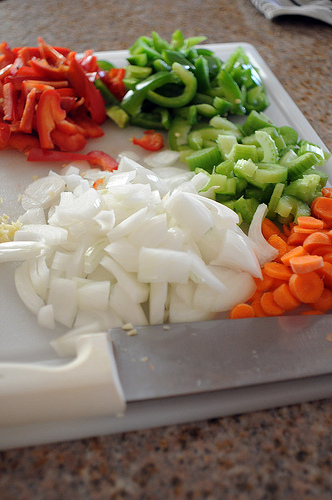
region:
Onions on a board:
[1, 157, 277, 350]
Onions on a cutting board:
[0, 150, 277, 356]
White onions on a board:
[0, 147, 276, 359]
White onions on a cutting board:
[1, 148, 277, 358]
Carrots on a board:
[221, 184, 330, 322]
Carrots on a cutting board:
[226, 181, 328, 320]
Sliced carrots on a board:
[229, 181, 323, 321]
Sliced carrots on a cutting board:
[228, 179, 331, 319]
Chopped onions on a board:
[6, 150, 278, 359]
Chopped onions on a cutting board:
[0, 148, 281, 357]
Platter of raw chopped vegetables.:
[4, 22, 318, 322]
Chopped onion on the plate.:
[20, 151, 256, 333]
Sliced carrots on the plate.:
[255, 187, 328, 312]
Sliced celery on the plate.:
[206, 104, 320, 205]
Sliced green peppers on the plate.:
[118, 11, 270, 125]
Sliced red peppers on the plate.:
[4, 27, 113, 161]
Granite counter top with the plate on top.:
[170, 418, 308, 488]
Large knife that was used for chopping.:
[10, 303, 326, 424]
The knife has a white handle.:
[6, 302, 328, 410]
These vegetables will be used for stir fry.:
[11, 37, 324, 317]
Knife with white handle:
[0, 320, 329, 422]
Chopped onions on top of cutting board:
[0, 162, 260, 325]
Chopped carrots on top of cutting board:
[231, 186, 329, 317]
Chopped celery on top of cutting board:
[171, 109, 328, 217]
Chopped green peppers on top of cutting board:
[102, 30, 269, 127]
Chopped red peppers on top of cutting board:
[1, 37, 163, 165]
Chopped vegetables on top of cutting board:
[2, 31, 331, 325]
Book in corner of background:
[251, 1, 330, 30]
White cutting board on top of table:
[1, 40, 330, 447]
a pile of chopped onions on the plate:
[27, 168, 177, 322]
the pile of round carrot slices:
[256, 215, 326, 316]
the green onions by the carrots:
[200, 116, 320, 189]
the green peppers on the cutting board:
[121, 25, 265, 119]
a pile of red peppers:
[0, 22, 114, 157]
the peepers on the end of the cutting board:
[0, 21, 259, 119]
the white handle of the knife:
[0, 332, 119, 410]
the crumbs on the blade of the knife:
[122, 316, 178, 336]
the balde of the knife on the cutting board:
[100, 314, 328, 414]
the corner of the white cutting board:
[242, 38, 329, 141]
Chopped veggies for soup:
[0, 30, 327, 330]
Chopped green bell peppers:
[122, 31, 262, 114]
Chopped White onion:
[20, 169, 248, 314]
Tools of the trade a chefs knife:
[3, 315, 329, 423]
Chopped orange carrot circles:
[249, 188, 331, 315]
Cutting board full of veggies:
[1, 39, 331, 449]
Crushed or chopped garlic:
[0, 218, 17, 243]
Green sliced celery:
[187, 114, 322, 215]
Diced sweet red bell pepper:
[1, 35, 110, 156]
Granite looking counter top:
[0, 1, 330, 499]